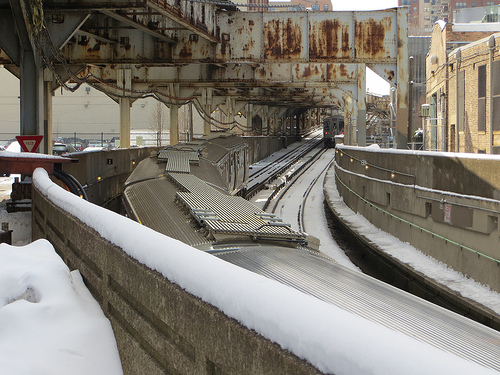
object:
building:
[423, 19, 499, 154]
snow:
[0, 235, 123, 374]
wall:
[32, 167, 498, 375]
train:
[321, 114, 344, 147]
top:
[325, 111, 345, 120]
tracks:
[241, 128, 336, 254]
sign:
[14, 134, 45, 153]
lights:
[325, 131, 328, 134]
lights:
[390, 174, 396, 178]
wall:
[333, 144, 499, 291]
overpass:
[1, 0, 409, 211]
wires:
[209, 123, 236, 130]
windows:
[476, 97, 486, 133]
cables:
[52, 168, 88, 202]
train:
[117, 134, 500, 374]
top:
[188, 242, 499, 373]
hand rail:
[335, 147, 415, 181]